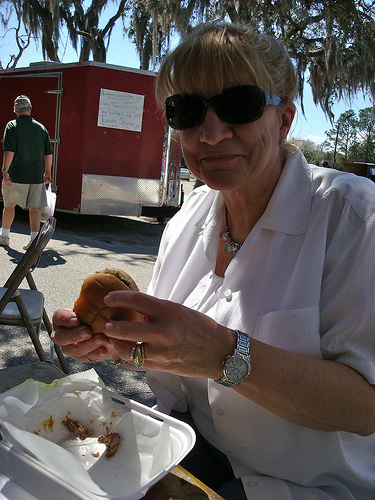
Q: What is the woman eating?
A: A hamburger.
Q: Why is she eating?
A: She is hungry.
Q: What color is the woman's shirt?
A: White.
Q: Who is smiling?
A: The woman.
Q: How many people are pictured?
A: Two.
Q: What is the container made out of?
A: Styrofoam.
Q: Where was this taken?
A: Outside a food truck.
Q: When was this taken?
A: Daytime.